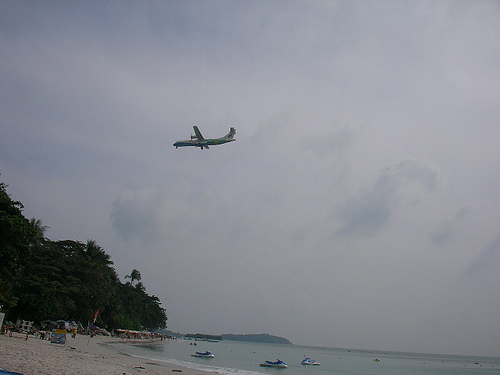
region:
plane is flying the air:
[158, 113, 261, 180]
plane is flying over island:
[25, 54, 295, 367]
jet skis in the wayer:
[177, 342, 344, 374]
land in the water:
[160, 308, 325, 358]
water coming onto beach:
[75, 328, 232, 373]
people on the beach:
[23, 305, 189, 358]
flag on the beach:
[68, 296, 150, 366]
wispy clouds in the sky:
[331, 162, 453, 275]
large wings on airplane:
[163, 108, 250, 173]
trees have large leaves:
[23, 212, 121, 288]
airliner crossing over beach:
[169, 103, 268, 150]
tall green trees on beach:
[38, 238, 147, 317]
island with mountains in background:
[199, 302, 326, 359]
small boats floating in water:
[272, 355, 283, 367]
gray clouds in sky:
[284, 138, 479, 273]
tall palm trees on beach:
[19, 192, 133, 284]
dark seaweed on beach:
[124, 360, 154, 370]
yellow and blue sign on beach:
[38, 323, 72, 343]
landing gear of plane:
[155, 145, 220, 152]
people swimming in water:
[192, 342, 204, 351]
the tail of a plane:
[218, 127, 237, 144]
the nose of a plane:
[171, 139, 185, 148]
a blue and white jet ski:
[258, 356, 286, 369]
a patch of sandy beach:
[0, 343, 134, 373]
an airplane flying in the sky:
[171, 124, 238, 150]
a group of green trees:
[0, 185, 173, 326]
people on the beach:
[113, 327, 170, 342]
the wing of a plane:
[193, 124, 203, 141]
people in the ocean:
[187, 340, 197, 347]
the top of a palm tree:
[122, 268, 142, 285]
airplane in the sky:
[159, 113, 244, 169]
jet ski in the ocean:
[184, 343, 217, 361]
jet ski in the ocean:
[260, 351, 284, 370]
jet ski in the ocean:
[295, 348, 323, 373]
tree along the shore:
[0, 190, 25, 316]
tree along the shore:
[28, 223, 48, 318]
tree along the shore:
[53, 240, 88, 321]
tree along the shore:
[111, 269, 136, 321]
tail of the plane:
[221, 125, 243, 150]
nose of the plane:
[168, 135, 193, 157]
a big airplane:
[171, 125, 238, 147]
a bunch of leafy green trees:
[0, 178, 169, 335]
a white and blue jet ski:
[258, 356, 288, 370]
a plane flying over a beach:
[129, 118, 331, 374]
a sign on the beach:
[48, 328, 68, 343]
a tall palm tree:
[125, 268, 141, 283]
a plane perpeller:
[188, 133, 195, 140]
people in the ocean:
[183, 339, 203, 351]